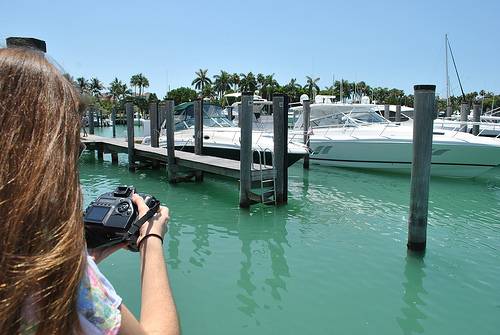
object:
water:
[75, 122, 498, 335]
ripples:
[163, 207, 313, 313]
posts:
[271, 94, 289, 212]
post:
[407, 83, 436, 251]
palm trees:
[128, 72, 151, 97]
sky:
[0, 0, 500, 100]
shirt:
[0, 246, 125, 335]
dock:
[77, 132, 289, 208]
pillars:
[405, 82, 440, 257]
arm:
[120, 231, 183, 335]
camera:
[83, 184, 161, 252]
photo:
[0, 0, 499, 335]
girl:
[0, 37, 182, 335]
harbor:
[0, 0, 500, 335]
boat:
[141, 96, 315, 175]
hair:
[0, 37, 87, 335]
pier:
[84, 102, 101, 135]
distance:
[1, 0, 498, 125]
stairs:
[252, 186, 278, 208]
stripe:
[307, 156, 500, 168]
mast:
[445, 34, 467, 116]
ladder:
[252, 147, 277, 206]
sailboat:
[400, 32, 500, 135]